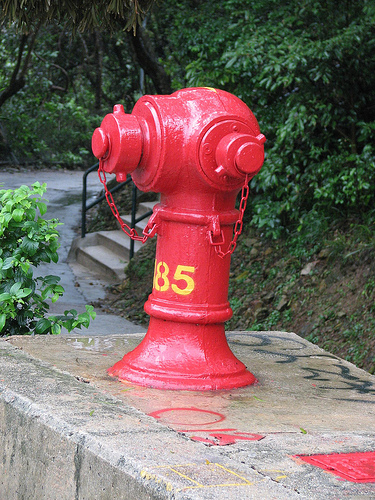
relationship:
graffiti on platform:
[230, 318, 374, 409] [3, 305, 371, 497]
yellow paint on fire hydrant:
[146, 255, 198, 297] [83, 83, 266, 389]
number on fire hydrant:
[170, 264, 197, 296] [83, 83, 266, 389]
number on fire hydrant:
[150, 262, 171, 292] [83, 83, 266, 389]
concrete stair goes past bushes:
[96, 229, 141, 262] [86, 7, 373, 368]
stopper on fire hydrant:
[91, 98, 162, 184] [83, 83, 266, 389]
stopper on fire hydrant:
[197, 119, 267, 187] [83, 83, 266, 389]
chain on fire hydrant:
[97, 159, 151, 242] [92, 85, 267, 391]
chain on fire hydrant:
[199, 169, 257, 257] [92, 85, 267, 391]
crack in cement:
[109, 390, 238, 489] [0, 331, 375, 500]